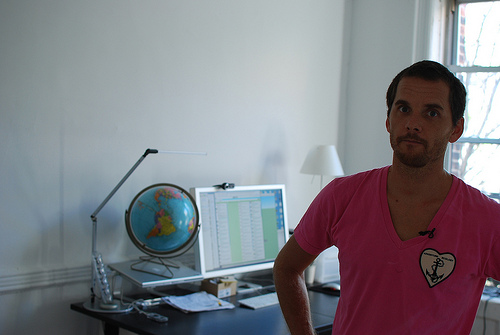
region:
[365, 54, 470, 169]
An unshaven man with dark hair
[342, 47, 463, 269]
An unshaven man with dark hair wearing a pink shirt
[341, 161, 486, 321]
The shirt is pink with a vee neck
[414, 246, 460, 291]
A heart with an anchor in it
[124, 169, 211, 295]
A globe on the desk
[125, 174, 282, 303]
A globe on the desk next to a computer monitor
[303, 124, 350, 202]
A lamp with a white shade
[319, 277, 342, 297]
A silver computer mouse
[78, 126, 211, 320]
A tall reading lamp with LED bulbs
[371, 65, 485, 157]
man has short hair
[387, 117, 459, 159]
man has short moustache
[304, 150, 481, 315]
man has pink shirt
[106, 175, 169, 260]
globe next to monitor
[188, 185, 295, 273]
grey frame on monitor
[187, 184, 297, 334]
monitor on black table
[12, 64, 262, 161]
white wall behind monitor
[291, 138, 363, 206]
white lamp in corner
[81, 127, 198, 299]
grey light over globe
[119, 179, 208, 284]
a world map on a desk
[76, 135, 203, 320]
a desk lamp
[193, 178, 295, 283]
the screen of a computer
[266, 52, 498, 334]
man wears a pink shirt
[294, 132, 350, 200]
a white lamp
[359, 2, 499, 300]
a window behind a man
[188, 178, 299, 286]
frame of computer is silver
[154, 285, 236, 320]
paper over a desk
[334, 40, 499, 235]
man has a goatee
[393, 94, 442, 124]
two brown eyes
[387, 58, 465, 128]
short cut black hair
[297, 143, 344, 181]
a small white lampshade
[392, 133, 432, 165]
a man's black beard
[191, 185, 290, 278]
a silver laptop computer monitor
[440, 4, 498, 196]
part of a window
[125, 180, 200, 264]
a small globe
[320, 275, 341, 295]
a computer mouse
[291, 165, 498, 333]
part of a man's pink shirt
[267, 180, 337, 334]
the arm of a man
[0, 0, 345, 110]
part of a white wall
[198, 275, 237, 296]
small cardboard box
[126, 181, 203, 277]
blue globe on a silver base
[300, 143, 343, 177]
white lamp shade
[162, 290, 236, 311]
papers on the desk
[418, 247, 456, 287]
heart with an anchor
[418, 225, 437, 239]
small mic pinned to his shirt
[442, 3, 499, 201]
part of a window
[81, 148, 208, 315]
adjustable metal silver desk lamp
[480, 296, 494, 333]
short section of a black cord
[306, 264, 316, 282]
white disposable coffee cup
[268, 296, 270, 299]
A key on a keyboard.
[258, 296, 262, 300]
A key on a keyboard.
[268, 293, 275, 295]
A key on a keyboard.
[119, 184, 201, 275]
a small blue globe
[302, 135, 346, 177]
a small white lampshade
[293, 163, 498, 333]
a man's short sleeve pink shirt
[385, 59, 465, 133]
a man's short cut hair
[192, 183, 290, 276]
a large computer screen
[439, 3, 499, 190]
a window of a home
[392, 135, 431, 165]
a man's beard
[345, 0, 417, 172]
a white painted wall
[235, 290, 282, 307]
a white computer keyboard